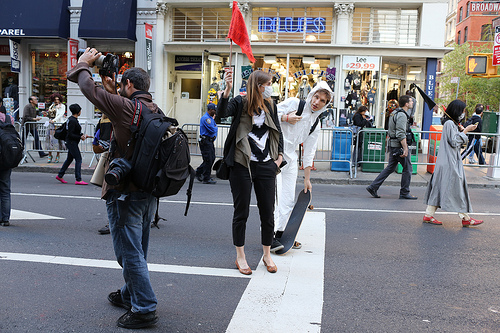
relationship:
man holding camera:
[64, 42, 178, 328] [73, 48, 122, 84]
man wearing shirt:
[64, 42, 178, 328] [65, 62, 173, 202]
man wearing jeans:
[64, 42, 178, 328] [104, 182, 167, 315]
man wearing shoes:
[64, 42, 178, 328] [117, 304, 162, 329]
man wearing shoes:
[104, 287, 133, 312] [103, 284, 140, 318]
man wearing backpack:
[64, 42, 178, 328] [127, 94, 201, 218]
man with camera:
[64, 42, 178, 328] [73, 48, 122, 84]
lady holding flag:
[215, 67, 291, 279] [224, 5, 256, 65]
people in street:
[421, 91, 489, 240] [1, 167, 500, 332]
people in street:
[364, 92, 424, 206] [1, 167, 500, 332]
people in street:
[261, 73, 336, 260] [1, 167, 500, 332]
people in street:
[192, 101, 226, 189] [1, 167, 500, 332]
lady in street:
[215, 67, 291, 279] [1, 167, 500, 332]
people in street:
[50, 101, 92, 188] [1, 167, 500, 332]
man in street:
[64, 42, 178, 328] [1, 167, 500, 332]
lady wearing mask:
[215, 67, 291, 279] [256, 80, 276, 104]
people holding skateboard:
[261, 73, 336, 260] [273, 189, 317, 255]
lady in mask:
[215, 67, 291, 279] [256, 80, 276, 104]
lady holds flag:
[215, 67, 291, 279] [224, 5, 256, 65]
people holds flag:
[421, 91, 489, 240] [413, 85, 436, 113]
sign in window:
[254, 12, 327, 44] [245, 6, 337, 48]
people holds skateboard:
[261, 73, 336, 260] [273, 189, 317, 255]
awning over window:
[76, 1, 137, 49] [88, 50, 140, 118]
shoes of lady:
[260, 252, 282, 275] [215, 67, 291, 279]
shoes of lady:
[234, 257, 252, 278] [215, 67, 291, 279]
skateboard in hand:
[273, 189, 317, 255] [301, 177, 315, 196]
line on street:
[219, 201, 336, 333] [1, 167, 500, 332]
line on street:
[1, 247, 258, 282] [1, 167, 500, 332]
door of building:
[171, 70, 207, 136] [155, 5, 452, 158]